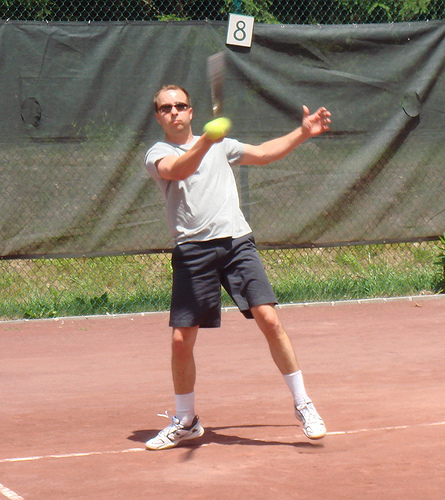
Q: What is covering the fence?
A: Black mesh.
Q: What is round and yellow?
A: Tennis ball.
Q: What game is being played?
A: Tennis.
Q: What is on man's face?
A: Sunglasses.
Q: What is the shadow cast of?
A: Tennis player.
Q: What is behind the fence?
A: Grass and weeds.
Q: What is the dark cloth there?
A: Vision.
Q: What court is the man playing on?
A: Eight.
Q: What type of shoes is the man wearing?
A: Sneakers.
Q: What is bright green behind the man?
A: Grass.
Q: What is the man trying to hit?
A: A tennis ball.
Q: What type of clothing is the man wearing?
A: Black shorts.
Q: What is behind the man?
A: A chain-link fence.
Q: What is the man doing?
A: Playing tennis.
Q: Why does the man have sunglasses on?
A: To protect his eyes from the sun.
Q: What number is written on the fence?
A: Eight.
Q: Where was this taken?
A: On a tennis court.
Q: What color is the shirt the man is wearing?
A: Gray.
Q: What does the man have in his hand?
A: A tennis racket.